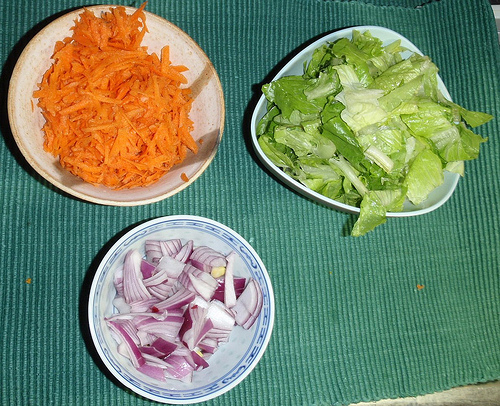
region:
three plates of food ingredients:
[2, 4, 499, 404]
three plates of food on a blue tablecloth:
[2, 3, 498, 400]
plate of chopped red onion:
[87, 214, 276, 403]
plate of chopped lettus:
[249, 23, 492, 238]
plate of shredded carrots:
[10, 6, 223, 207]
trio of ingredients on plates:
[9, 3, 469, 403]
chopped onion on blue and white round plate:
[87, 214, 276, 403]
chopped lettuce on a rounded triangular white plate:
[253, 21, 491, 238]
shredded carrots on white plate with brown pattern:
[10, 4, 227, 206]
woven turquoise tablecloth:
[1, 5, 499, 404]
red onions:
[125, 275, 239, 356]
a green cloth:
[277, 238, 383, 319]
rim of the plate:
[227, 359, 249, 374]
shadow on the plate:
[191, 130, 218, 158]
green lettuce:
[300, 80, 426, 167]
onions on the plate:
[118, 313, 192, 370]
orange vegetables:
[72, 76, 155, 144]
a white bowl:
[280, 58, 303, 73]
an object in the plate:
[213, 265, 229, 279]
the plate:
[7, 80, 37, 98]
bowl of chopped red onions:
[86, 211, 276, 404]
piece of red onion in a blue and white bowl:
[224, 248, 241, 307]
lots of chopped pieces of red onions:
[106, 238, 263, 380]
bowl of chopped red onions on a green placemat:
[81, 213, 289, 404]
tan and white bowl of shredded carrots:
[4, 2, 227, 208]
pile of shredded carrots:
[31, 4, 196, 188]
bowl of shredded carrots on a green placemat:
[3, 3, 227, 207]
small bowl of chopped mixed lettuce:
[247, 25, 497, 237]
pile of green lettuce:
[261, 28, 495, 237]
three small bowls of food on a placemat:
[1, 0, 496, 404]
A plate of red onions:
[84, 213, 274, 403]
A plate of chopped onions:
[87, 215, 274, 402]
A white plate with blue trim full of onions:
[85, 213, 276, 404]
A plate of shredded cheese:
[3, 5, 221, 203]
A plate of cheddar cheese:
[10, 3, 225, 204]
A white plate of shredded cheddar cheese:
[9, 5, 224, 205]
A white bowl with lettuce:
[250, 25, 465, 216]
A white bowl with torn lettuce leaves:
[247, 25, 466, 215]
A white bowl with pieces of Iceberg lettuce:
[250, 25, 465, 216]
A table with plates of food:
[3, 1, 495, 404]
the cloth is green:
[289, 287, 377, 348]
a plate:
[235, 350, 267, 372]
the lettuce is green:
[284, 85, 399, 148]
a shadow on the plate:
[189, 135, 219, 165]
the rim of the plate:
[228, 366, 245, 383]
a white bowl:
[404, 200, 429, 217]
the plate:
[8, 116, 42, 148]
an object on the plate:
[206, 262, 226, 276]